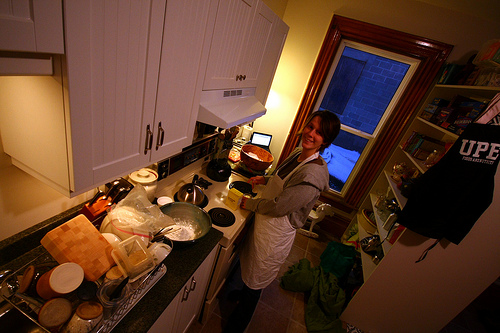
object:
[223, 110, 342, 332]
woman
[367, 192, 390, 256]
pantry shelves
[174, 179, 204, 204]
kettle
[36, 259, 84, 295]
dish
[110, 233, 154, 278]
dish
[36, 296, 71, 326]
dish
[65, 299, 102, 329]
dish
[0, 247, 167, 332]
dish drainer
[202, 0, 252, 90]
cabinet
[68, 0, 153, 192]
cabinet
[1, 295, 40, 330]
sink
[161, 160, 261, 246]
stove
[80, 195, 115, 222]
block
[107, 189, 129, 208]
knives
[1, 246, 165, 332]
cutting board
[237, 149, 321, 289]
apron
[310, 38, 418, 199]
door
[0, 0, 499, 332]
kitchen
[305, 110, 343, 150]
hair